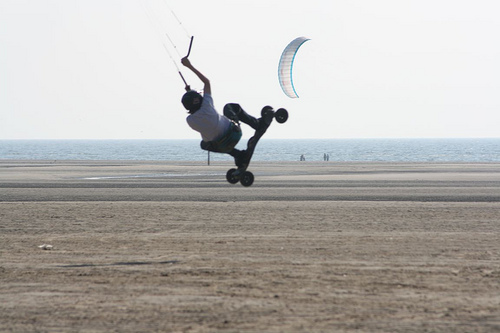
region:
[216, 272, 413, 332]
ground covered in sand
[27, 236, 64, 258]
grey rock laying on beach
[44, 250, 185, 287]
shadow of person on beach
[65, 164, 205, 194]
water standing on beach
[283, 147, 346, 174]
people standing beside water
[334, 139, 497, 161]
surface of ocean water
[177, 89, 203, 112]
black safety helmet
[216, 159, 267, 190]
two black wheels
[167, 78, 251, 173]
person in white shirt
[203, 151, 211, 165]
wooden sign pole on beach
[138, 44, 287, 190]
person in the air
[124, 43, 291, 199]
person holding something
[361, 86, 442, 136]
white sky above ocean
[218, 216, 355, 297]
brown sand beneath guy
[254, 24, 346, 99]
blue and white object flying over ocean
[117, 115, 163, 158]
ocean next to beach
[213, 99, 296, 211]
four wheels on object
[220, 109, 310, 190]
object underneath a person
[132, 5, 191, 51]
strings that man is holding onto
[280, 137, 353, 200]
people in the background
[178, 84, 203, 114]
the head of a man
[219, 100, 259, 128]
the leg of a man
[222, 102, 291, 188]
a skateboard under the man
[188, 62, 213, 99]
the arm of a man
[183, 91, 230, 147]
a white tee shirt on the man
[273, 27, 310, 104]
a kite in the sky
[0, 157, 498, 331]
a brown sandy beach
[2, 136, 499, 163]
calm blue ocean water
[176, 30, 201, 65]
a black handle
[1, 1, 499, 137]
a gray sky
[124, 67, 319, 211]
person doing a trick on a board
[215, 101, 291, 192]
a rough terrain skateboard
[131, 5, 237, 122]
handles of a parasail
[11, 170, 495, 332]
A beach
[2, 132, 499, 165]
the ocean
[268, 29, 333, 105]
a parasail in the sky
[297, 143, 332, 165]
a group of people close to the water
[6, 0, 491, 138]
a grey sky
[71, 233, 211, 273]
shadow cast by the man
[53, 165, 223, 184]
some water on the beach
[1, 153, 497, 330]
the sand is tan.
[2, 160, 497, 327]
sand on the ground.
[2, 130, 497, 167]
the water is blue.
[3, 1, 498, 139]
the sky is grey.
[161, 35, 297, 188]
man in the air.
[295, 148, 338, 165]
people walking on the beach.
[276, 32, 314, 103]
kite in the sky.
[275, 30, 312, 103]
the kite is blue and white.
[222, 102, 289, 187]
the board is black.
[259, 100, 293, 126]
the wheel is round.